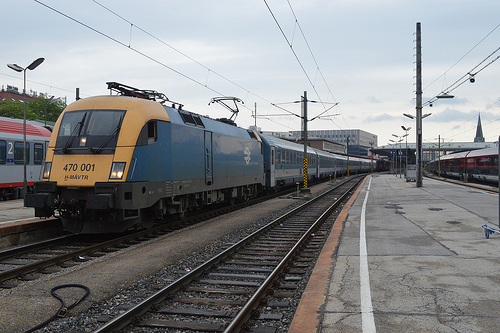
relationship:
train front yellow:
[17, 83, 390, 239] [44, 90, 172, 190]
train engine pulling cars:
[33, 87, 268, 227] [265, 129, 389, 186]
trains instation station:
[17, 83, 390, 239] [6, 160, 500, 332]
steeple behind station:
[469, 105, 488, 136] [363, 121, 500, 171]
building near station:
[267, 124, 384, 146] [6, 160, 500, 332]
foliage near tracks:
[3, 85, 66, 118] [0, 179, 361, 332]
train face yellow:
[17, 83, 390, 239] [44, 90, 172, 190]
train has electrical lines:
[17, 83, 390, 239] [32, 1, 500, 86]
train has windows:
[17, 83, 390, 239] [51, 111, 128, 155]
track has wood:
[0, 229, 327, 331] [217, 256, 271, 282]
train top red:
[1, 109, 49, 202] [3, 116, 48, 136]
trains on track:
[17, 83, 390, 239] [0, 229, 327, 331]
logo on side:
[235, 140, 260, 169] [153, 140, 321, 180]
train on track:
[17, 83, 390, 239] [0, 210, 150, 285]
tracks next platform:
[219, 187, 369, 326] [305, 170, 499, 326]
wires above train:
[32, 1, 500, 86] [17, 83, 390, 239]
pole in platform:
[407, 20, 436, 189] [305, 170, 499, 326]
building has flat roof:
[267, 124, 384, 146] [264, 126, 385, 134]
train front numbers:
[17, 83, 390, 239] [60, 160, 99, 175]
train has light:
[17, 83, 390, 239] [40, 159, 127, 180]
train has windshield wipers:
[17, 83, 390, 239] [57, 111, 125, 156]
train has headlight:
[17, 83, 390, 239] [71, 130, 95, 149]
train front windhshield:
[17, 83, 390, 239] [57, 111, 125, 156]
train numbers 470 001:
[17, 83, 390, 239] [60, 160, 99, 175]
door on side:
[200, 124, 216, 188] [153, 140, 321, 180]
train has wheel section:
[17, 83, 390, 239] [140, 177, 338, 227]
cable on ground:
[11, 278, 92, 333] [11, 238, 136, 332]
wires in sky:
[32, 1, 500, 86] [2, 2, 484, 142]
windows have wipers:
[51, 109, 131, 154] [57, 111, 125, 156]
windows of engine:
[51, 109, 131, 154] [39, 90, 269, 230]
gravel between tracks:
[165, 215, 274, 279] [0, 229, 327, 331]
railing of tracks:
[222, 177, 358, 331] [0, 229, 327, 331]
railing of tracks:
[87, 174, 350, 331] [0, 229, 327, 331]